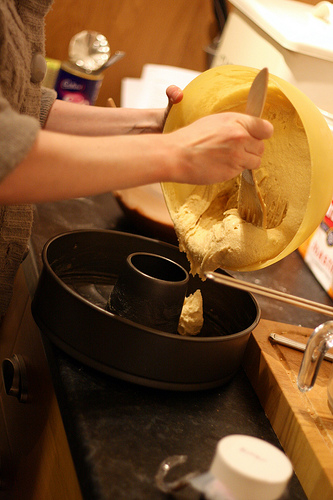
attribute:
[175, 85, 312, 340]
cake mixture — yellow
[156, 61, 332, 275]
mixing bowl — yellow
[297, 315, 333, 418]
jug — glass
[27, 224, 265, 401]
cake tin — black, ring shaped, non stick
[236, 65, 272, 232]
spatula — wooden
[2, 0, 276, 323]
person — baking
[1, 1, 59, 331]
sweater — grey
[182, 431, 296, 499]
measuring cup — glass, white, upside down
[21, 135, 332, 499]
counter — black, granite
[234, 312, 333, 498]
chopping board — wooden